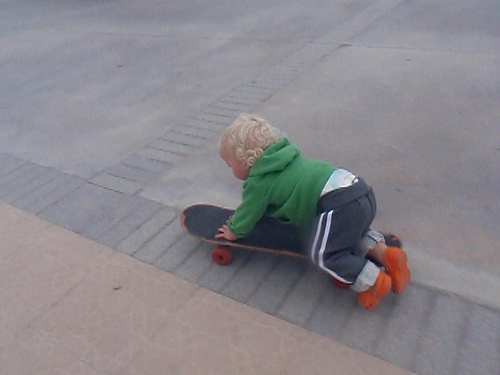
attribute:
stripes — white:
[310, 206, 354, 286]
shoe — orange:
[387, 249, 410, 301]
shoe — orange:
[358, 275, 393, 310]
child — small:
[204, 105, 415, 313]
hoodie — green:
[230, 132, 369, 234]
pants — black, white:
[308, 177, 380, 296]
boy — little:
[209, 108, 414, 318]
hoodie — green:
[235, 137, 323, 237]